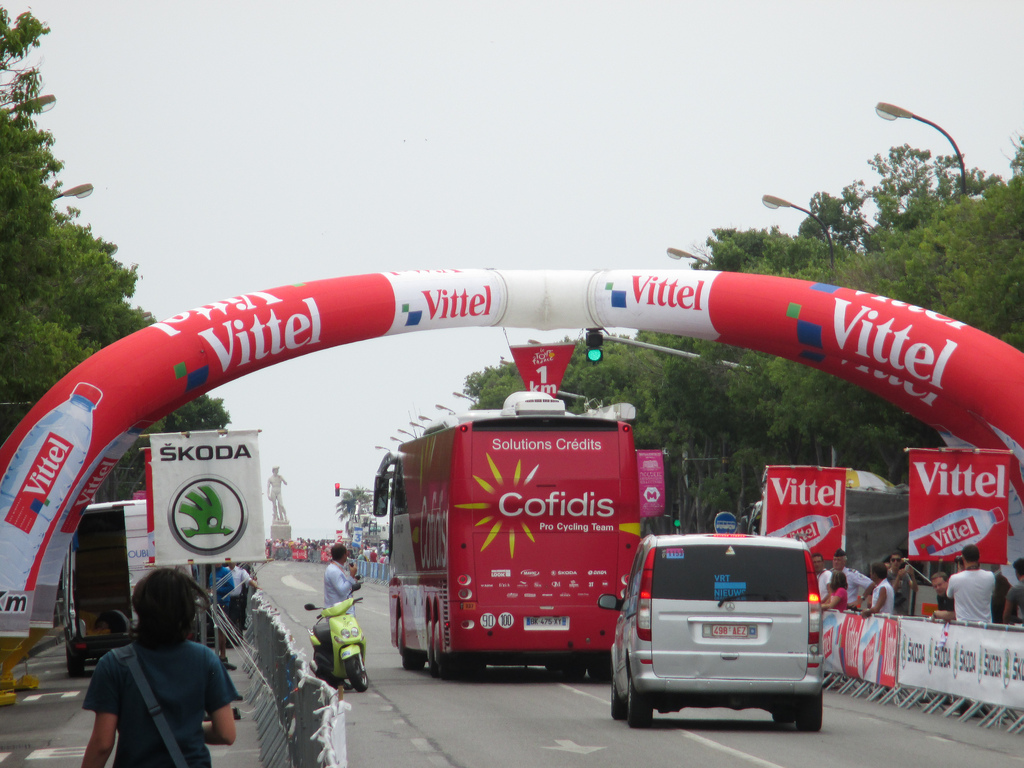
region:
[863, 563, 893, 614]
man wearing a white shirt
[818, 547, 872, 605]
man wearing a white shirt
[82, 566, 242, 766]
woman wearing a blue shirt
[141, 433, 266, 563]
sign with skoda business logo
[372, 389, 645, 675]
big red city bus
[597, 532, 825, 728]
rear end of a grey SUV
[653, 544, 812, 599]
grey car's rear window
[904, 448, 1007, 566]
Vittel business logo sign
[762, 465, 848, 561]
Vittel business logo sign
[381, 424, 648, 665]
a large red bus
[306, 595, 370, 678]
a green motorcycle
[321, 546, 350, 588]
a man standing by the bus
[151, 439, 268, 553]
a white flag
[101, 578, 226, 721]
a person in a black shirt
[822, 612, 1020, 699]
a white fence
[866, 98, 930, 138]
a street lamp post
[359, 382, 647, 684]
red double decker bus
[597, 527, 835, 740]
grey van driving down street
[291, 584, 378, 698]
green motorcycle on side of street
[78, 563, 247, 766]
woman walking with blue short sleeve shirt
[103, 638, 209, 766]
messenger bag strap across woman's back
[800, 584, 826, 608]
orange light on back of silver car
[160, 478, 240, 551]
green logo on white sign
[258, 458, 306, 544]
white statue of a man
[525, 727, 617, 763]
white arrow on street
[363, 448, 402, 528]
rear view mirror on bus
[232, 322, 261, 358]
letter on the sign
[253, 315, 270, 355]
letter on the sign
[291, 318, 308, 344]
letter on the sign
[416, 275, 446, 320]
letter on the sign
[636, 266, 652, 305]
letter on the sign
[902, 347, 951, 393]
letter on the sign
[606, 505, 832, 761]
white van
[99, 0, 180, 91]
white clouds in blue sky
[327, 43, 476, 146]
white clouds in blue sky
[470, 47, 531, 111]
white clouds in blue sky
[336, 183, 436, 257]
white clouds in blue sky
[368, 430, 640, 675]
a large red bus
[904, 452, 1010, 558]
a large red and white flag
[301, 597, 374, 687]
a small green motorcycle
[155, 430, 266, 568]
a large green, black and white flag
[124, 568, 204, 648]
a woman's black hair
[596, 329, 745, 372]
a long pole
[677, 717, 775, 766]
a long white painted line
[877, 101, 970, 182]
the top of a street light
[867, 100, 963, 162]
a lamp post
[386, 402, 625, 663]
a large red bus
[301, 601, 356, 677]
a green scooter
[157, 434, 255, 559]
a white sign hanging over the street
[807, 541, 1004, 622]
people standing next to the street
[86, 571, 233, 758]
a person in a grey shirt